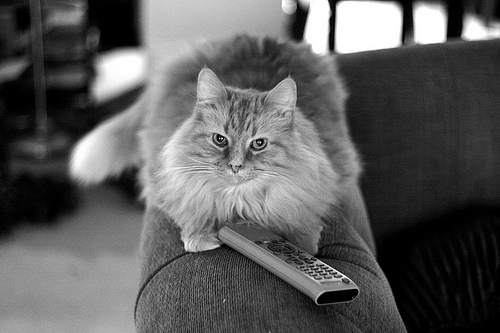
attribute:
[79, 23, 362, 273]
cat — long, fluffy, fluffly, happy, furry, on, gray, white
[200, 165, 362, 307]
control — remote, power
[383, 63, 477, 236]
couch — comfy